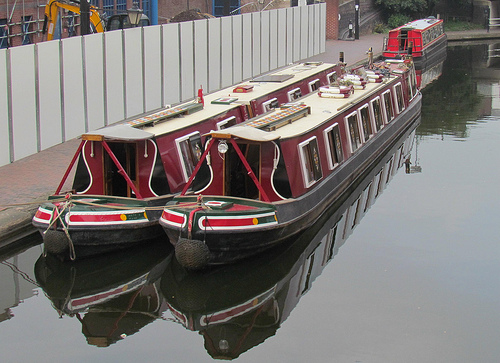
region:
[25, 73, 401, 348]
The boats are parked side by side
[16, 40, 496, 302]
Some boats are parked in a river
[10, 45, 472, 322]
Some boats are designed to carry people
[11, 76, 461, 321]
Some boats are there for vacationers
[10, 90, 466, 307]
The boats are in calm water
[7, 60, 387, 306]
The boats are tied together well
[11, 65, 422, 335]
The boats carry good safety equipment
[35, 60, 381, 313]
The boats can be rented for money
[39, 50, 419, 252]
the boats are on the water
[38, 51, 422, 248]
the boats are red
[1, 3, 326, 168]
the wall is striped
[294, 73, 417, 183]
the boats have windows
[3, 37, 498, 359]
the water is murky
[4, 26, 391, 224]
the sidewalk is red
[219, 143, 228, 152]
the boat has a headlight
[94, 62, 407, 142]
the boat roof is yellow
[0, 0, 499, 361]
scene takes place outdoors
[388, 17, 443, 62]
the boat is red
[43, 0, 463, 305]
three boats in the water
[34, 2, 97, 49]
part of a yelllow construction vehicle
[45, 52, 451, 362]
reflection of boats on the water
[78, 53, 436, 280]
two long red and black boats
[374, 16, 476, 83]
one boat parked alone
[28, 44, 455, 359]
two boats docked together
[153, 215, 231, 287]
black bumper on front of boat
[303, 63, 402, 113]
red and white life preservers on top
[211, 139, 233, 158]
a light on front of boat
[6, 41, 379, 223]
a brick walkway next to boat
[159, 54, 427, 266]
long green and red boat sitting in water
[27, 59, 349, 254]
long red and green boat sitting in water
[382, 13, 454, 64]
long green and red boat sitting in water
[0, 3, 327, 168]
long white barrier posted on a sidewalk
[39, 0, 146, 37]
yellow tractor parked behind long white barrier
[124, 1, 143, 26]
black lamp post posted behind long white barrier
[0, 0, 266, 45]
huge tan and blue building behind white barrier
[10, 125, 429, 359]
reflections of boats in water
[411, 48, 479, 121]
reflection of trees in water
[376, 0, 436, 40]
trees posted on the sidewalk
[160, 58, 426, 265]
red black and white boat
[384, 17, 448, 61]
red and grey boat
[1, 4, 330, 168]
grey cement barrier wall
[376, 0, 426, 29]
bush with green leaves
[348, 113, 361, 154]
window on side of boat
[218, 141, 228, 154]
light hanging on boat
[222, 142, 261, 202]
front door opening on boat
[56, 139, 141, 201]
red metal support poles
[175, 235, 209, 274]
black bumper on boat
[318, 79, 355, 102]
life rafts on boat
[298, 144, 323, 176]
a window on the boat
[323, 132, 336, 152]
a window on the boat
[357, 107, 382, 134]
a window on the boat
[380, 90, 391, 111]
a window on the boat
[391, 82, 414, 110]
a window on the boat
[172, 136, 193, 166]
a window on the boat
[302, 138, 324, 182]
A window on a boat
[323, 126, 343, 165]
A window on a boat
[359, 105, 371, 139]
A window on a boat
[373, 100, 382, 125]
A window on a boat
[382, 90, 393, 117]
A window on a boat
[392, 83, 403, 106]
A window on a boat